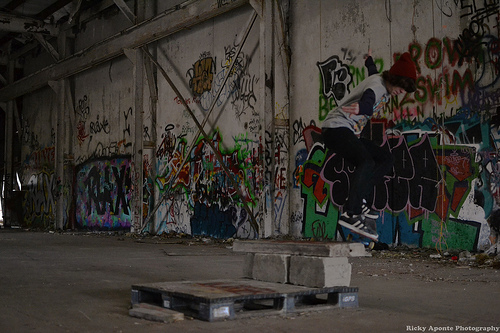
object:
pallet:
[129, 277, 359, 324]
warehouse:
[0, 0, 500, 333]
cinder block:
[289, 256, 353, 288]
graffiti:
[290, 11, 500, 260]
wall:
[0, 0, 500, 271]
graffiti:
[183, 52, 219, 97]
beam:
[128, 44, 148, 236]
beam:
[48, 78, 73, 233]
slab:
[232, 240, 370, 257]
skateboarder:
[319, 42, 417, 241]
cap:
[388, 53, 422, 79]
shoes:
[337, 213, 381, 241]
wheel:
[368, 241, 376, 252]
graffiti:
[67, 144, 131, 232]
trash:
[430, 243, 500, 271]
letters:
[317, 96, 331, 122]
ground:
[0, 230, 498, 333]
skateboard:
[342, 230, 376, 251]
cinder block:
[250, 253, 291, 286]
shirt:
[322, 73, 389, 135]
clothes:
[318, 126, 375, 217]